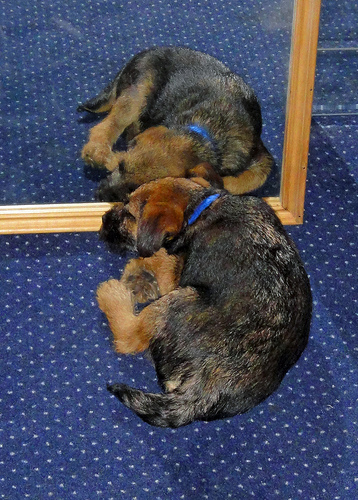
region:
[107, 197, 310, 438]
dog in front of mirror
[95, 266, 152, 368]
dog has brown paws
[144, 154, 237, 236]
dog has blue collar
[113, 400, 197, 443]
dog has black tail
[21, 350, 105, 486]
blue and white carpet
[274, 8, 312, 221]
brown frame around mirror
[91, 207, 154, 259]
dog has black nose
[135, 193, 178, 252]
brown and black ears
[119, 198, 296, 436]
dog is lying down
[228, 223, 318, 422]
black fur on back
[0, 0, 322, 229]
raised wood frame around mirror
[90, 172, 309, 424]
dog curled up in front of mirror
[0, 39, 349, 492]
royal-blue carpeting with white dots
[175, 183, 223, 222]
bright blue collar around neck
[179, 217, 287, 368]
shiny sheen on fur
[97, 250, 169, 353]
brown paws to side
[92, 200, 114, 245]
black mouth and nose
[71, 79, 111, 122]
short tail lifted off floor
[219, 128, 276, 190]
layer of round skin behind dog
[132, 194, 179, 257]
brown ear with darker edge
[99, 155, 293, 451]
the dog is sleeping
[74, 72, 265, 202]
a reflection of the dog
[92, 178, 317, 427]
A dog laying on the floor.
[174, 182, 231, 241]
a blue collar on a dog.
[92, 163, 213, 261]
the head of a brown dog.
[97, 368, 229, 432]
a tail on a small dog.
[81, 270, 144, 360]
a brown leg on a dog.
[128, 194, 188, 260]
a left fuzzy dog ear.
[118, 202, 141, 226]
a left eye on a dog.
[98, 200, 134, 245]
a mouth on a dog.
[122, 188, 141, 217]
the forehead of a dog.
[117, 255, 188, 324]
A left front paw.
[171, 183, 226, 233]
dog is wearing a collar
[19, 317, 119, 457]
the floor is carpeted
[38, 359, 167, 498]
the floor is carpeted